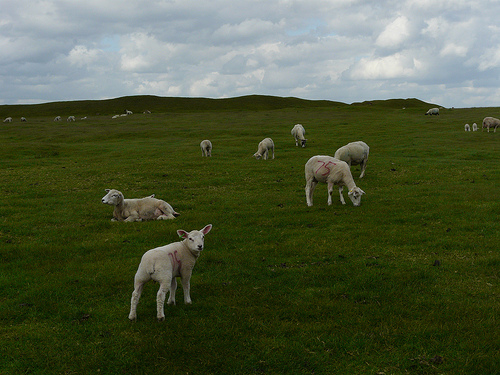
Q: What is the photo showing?
A: It is showing a field.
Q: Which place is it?
A: It is a field.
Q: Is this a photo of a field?
A: Yes, it is showing a field.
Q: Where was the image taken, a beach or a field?
A: It was taken at a field.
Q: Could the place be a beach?
A: No, it is a field.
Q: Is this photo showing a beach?
A: No, the picture is showing a field.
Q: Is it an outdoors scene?
A: Yes, it is outdoors.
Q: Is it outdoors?
A: Yes, it is outdoors.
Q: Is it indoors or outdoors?
A: It is outdoors.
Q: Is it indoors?
A: No, it is outdoors.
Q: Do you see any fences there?
A: No, there are no fences.